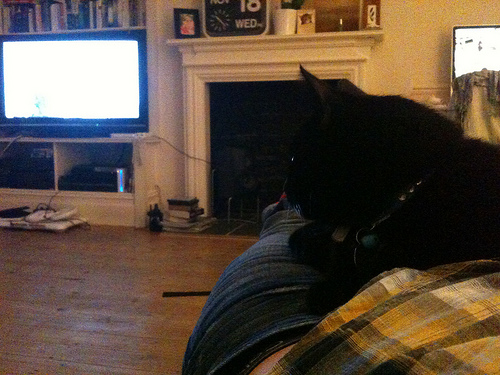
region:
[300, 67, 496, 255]
black cat wearing a bell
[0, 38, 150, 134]
flat screen television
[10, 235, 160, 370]
brown wood floor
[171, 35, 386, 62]
white fireplace mantel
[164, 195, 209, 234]
stack of books on the floor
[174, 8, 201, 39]
black photo frame on the mantel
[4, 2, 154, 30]
books lined up above the television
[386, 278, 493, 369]
black, white, and gold shirt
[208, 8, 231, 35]
black and white clock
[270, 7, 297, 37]
white flower pot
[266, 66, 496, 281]
a black cat is laying down on a sofa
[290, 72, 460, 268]
the cat has a collar on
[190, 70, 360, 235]
a fireplace is in the room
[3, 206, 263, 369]
the room has wooden floors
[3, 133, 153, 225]
the tv stand has electronics on the shelves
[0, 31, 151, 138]
the tv is on with a white screen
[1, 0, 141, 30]
book shelves are behind the tv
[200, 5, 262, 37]
a clock is on the mantle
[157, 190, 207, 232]
books are stacked next to the fireplace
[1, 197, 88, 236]
items are on the floor near the tv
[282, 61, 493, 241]
black cat watching TV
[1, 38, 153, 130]
flat screen tv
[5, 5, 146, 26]
books on a bookshelf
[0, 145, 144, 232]
entertainment boxes like DVD player and game consol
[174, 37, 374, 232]
black fireplace with white crown molding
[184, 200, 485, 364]
person wearing blue jeans and plaid yellow shirt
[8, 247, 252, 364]
hard wood floors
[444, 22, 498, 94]
bright window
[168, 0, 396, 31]
nick nacks like pitcures and clock on a mantle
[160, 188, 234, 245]
books stacked on the floor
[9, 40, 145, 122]
A big screen TV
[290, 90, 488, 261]
A black cat laying down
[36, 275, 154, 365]
A wooden floor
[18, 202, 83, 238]
A mess on the floor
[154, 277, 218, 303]
A TV remote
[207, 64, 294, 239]
A fireplace in the livingroom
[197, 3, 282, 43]
A black and white clock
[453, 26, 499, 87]
A Computer screen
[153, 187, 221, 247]
A pile of books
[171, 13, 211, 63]
A picture on the mantle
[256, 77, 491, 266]
Black cat looking at something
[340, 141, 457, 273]
Collar around cat's neck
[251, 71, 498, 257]
Cat relaxing on couch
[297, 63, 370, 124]
Pointy ear of cat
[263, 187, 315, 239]
Whiskers on side of cat's face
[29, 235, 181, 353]
Brown floor next to cat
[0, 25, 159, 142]
Bright television in room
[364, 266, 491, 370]
Patterned object next to cat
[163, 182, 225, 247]
Books next to fireplace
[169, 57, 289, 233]
Empty fireplace in room